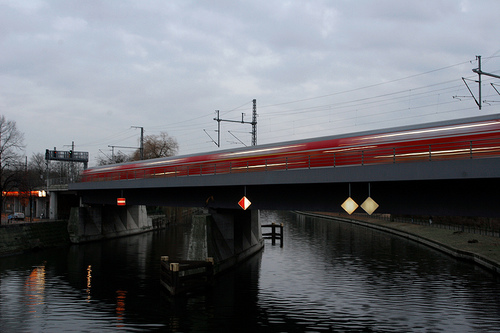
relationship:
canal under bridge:
[0, 207, 499, 332] [84, 120, 474, 182]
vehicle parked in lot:
[9, 210, 24, 220] [3, 210, 57, 228]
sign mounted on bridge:
[114, 193, 129, 208] [44, 97, 499, 204]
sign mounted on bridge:
[234, 192, 260, 210] [44, 97, 499, 204]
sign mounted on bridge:
[338, 190, 360, 220] [44, 97, 499, 204]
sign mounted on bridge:
[360, 192, 380, 219] [44, 97, 499, 204]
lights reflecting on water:
[17, 253, 122, 323] [12, 248, 478, 328]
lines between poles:
[316, 90, 380, 112] [230, 97, 259, 142]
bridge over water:
[39, 106, 497, 282] [1, 201, 498, 331]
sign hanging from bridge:
[234, 192, 260, 210] [36, 157, 498, 280]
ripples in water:
[238, 289, 345, 326] [12, 272, 482, 328]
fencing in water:
[261, 221, 284, 248] [266, 246, 327, 287]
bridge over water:
[34, 138, 499, 300] [6, 259, 473, 319]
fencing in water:
[263, 218, 286, 246] [248, 205, 476, 328]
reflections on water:
[16, 266, 132, 325] [1, 201, 498, 331]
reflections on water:
[16, 256, 119, 324] [1, 201, 498, 331]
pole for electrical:
[248, 96, 259, 145] [253, 56, 479, 144]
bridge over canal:
[34, 138, 499, 300] [4, 213, 476, 331]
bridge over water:
[34, 138, 499, 300] [1, 201, 498, 331]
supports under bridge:
[50, 192, 309, 251] [34, 138, 499, 300]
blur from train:
[296, 132, 389, 167] [76, 116, 497, 170]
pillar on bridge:
[102, 208, 152, 235] [127, 176, 296, 209]